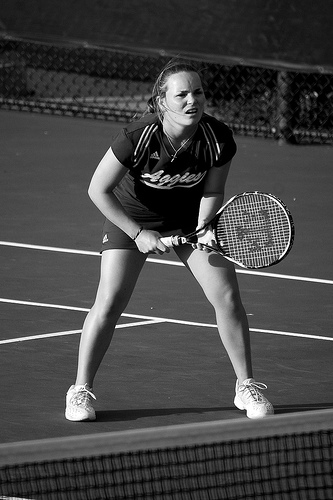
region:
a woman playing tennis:
[62, 57, 296, 420]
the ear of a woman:
[153, 92, 170, 114]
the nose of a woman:
[185, 92, 198, 105]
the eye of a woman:
[172, 90, 189, 100]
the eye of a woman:
[192, 86, 204, 97]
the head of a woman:
[144, 58, 218, 140]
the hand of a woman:
[130, 229, 170, 261]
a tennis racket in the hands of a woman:
[123, 185, 298, 270]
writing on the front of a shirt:
[139, 160, 207, 192]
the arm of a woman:
[85, 142, 171, 258]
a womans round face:
[153, 52, 206, 130]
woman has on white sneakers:
[59, 373, 299, 431]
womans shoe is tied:
[230, 358, 285, 430]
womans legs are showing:
[83, 238, 278, 352]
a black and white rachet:
[187, 181, 302, 282]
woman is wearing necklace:
[155, 126, 195, 179]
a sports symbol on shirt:
[144, 141, 166, 167]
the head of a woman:
[121, 52, 233, 154]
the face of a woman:
[143, 52, 249, 124]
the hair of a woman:
[143, 52, 221, 138]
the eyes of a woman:
[161, 88, 222, 107]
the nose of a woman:
[178, 94, 204, 113]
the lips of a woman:
[171, 99, 217, 140]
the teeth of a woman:
[174, 101, 213, 132]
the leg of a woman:
[50, 258, 155, 402]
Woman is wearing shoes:
[63, 371, 279, 422]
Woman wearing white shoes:
[60, 377, 275, 422]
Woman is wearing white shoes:
[61, 374, 279, 425]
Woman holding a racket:
[150, 186, 304, 272]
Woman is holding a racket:
[155, 189, 296, 271]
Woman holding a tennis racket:
[156, 187, 294, 271]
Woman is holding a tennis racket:
[156, 186, 298, 272]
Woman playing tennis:
[62, 50, 297, 421]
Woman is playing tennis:
[64, 58, 296, 423]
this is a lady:
[51, 64, 281, 428]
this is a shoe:
[58, 376, 105, 432]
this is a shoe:
[222, 362, 278, 422]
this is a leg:
[61, 214, 137, 417]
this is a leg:
[174, 218, 283, 423]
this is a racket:
[132, 178, 301, 284]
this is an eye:
[171, 84, 189, 100]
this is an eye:
[187, 78, 203, 103]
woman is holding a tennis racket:
[62, 60, 297, 419]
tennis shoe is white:
[65, 381, 94, 421]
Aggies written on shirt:
[112, 111, 236, 219]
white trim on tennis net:
[2, 409, 331, 498]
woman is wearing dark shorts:
[64, 55, 274, 423]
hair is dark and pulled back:
[147, 51, 204, 141]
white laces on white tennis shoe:
[232, 375, 274, 418]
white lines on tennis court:
[2, 109, 332, 491]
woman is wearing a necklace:
[65, 59, 275, 424]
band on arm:
[86, 126, 168, 254]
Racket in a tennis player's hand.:
[147, 190, 295, 268]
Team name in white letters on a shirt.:
[138, 168, 208, 190]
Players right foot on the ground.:
[61, 380, 100, 420]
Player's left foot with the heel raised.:
[232, 378, 275, 417]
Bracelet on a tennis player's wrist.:
[126, 222, 146, 241]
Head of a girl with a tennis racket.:
[156, 59, 204, 132]